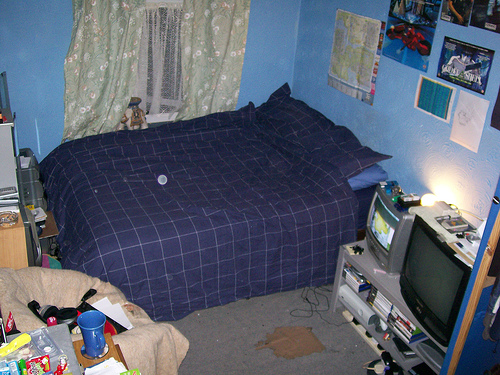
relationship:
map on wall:
[328, 8, 387, 98] [0, 0, 497, 231]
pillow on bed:
[255, 82, 395, 190] [31, 88, 391, 324]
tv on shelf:
[394, 212, 475, 349] [332, 237, 443, 372]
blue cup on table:
[76, 309, 108, 356] [71, 329, 122, 372]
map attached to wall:
[328, 8, 387, 98] [286, 0, 498, 216]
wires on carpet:
[288, 280, 349, 337] [192, 311, 258, 373]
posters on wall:
[332, 2, 500, 151] [302, 6, 497, 219]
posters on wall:
[332, 2, 500, 151] [306, 12, 495, 182]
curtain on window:
[73, 5, 143, 135] [73, 0, 245, 125]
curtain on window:
[180, 0, 245, 110] [73, 0, 245, 125]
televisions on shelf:
[364, 188, 478, 342] [341, 243, 371, 275]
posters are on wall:
[381, 2, 470, 99] [283, 9, 350, 60]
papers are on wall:
[446, 71, 496, 153] [283, 9, 350, 60]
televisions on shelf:
[364, 188, 415, 274] [339, 238, 445, 355]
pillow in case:
[255, 82, 395, 190] [254, 82, 337, 142]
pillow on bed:
[347, 169, 387, 191] [146, 96, 441, 244]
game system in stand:
[336, 289, 387, 328] [329, 239, 421, 361]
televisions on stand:
[364, 188, 415, 274] [324, 232, 456, 374]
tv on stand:
[398, 199, 487, 346] [324, 232, 456, 374]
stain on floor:
[253, 324, 327, 359] [156, 282, 386, 371]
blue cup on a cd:
[76, 309, 108, 356] [74, 339, 116, 357]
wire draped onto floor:
[291, 276, 351, 331] [156, 282, 386, 371]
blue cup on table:
[76, 309, 108, 356] [336, 215, 470, 369]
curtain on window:
[174, 0, 243, 125] [140, 25, 216, 135]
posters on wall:
[332, 2, 500, 151] [288, 67, 498, 244]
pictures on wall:
[316, 10, 498, 156] [295, 0, 499, 154]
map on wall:
[309, 26, 404, 123] [287, 75, 497, 232]